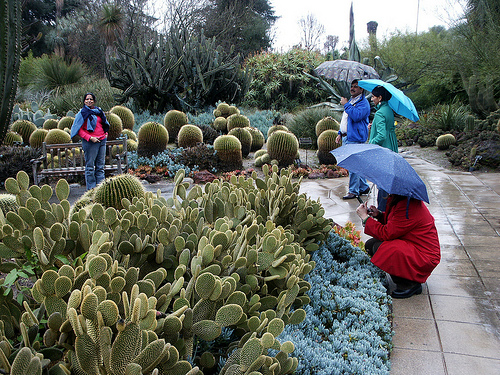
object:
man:
[333, 77, 372, 202]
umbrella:
[310, 56, 382, 86]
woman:
[363, 84, 399, 153]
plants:
[30, 225, 45, 256]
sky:
[136, 0, 469, 56]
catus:
[85, 253, 109, 285]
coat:
[363, 198, 442, 285]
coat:
[342, 95, 372, 154]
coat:
[366, 102, 400, 158]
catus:
[193, 270, 218, 302]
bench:
[27, 140, 133, 188]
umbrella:
[356, 76, 420, 126]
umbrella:
[326, 140, 428, 223]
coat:
[67, 106, 110, 142]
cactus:
[3, 175, 21, 198]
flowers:
[272, 236, 392, 374]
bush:
[278, 103, 345, 147]